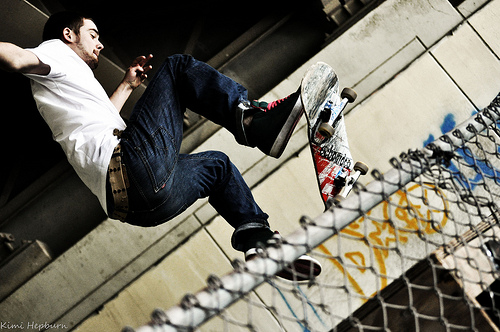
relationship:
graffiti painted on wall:
[291, 101, 499, 293] [4, 3, 498, 330]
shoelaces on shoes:
[262, 98, 292, 112] [252, 65, 306, 155]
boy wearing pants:
[2, 13, 322, 281] [107, 51, 269, 223]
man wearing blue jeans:
[2, 12, 371, 278] [110, 54, 310, 277]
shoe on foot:
[241, 84, 309, 159] [217, 30, 342, 167]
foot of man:
[217, 30, 342, 167] [2, 12, 371, 278]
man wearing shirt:
[2, 12, 371, 278] [24, 35, 125, 217]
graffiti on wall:
[291, 186, 466, 293] [4, 3, 498, 330]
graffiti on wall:
[291, 101, 499, 293] [4, 3, 498, 330]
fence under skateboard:
[121, 96, 498, 331] [301, 61, 368, 210]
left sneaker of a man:
[231, 222, 321, 287] [2, 12, 371, 278]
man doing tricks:
[2, 12, 371, 278] [1, 0, 389, 304]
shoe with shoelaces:
[241, 84, 309, 159] [262, 98, 292, 112]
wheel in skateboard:
[324, 194, 341, 209] [292, 58, 369, 215]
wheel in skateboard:
[351, 160, 371, 174] [292, 58, 369, 215]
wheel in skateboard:
[340, 86, 357, 103] [292, 58, 369, 215]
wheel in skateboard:
[317, 121, 335, 137] [292, 58, 369, 215]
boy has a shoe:
[2, 13, 322, 281] [176, 70, 373, 164]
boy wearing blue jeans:
[2, 13, 322, 281] [110, 54, 254, 226]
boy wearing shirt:
[2, 13, 322, 281] [32, 37, 133, 217]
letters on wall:
[317, 111, 497, 302] [4, 3, 498, 330]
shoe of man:
[241, 84, 309, 159] [2, 12, 371, 278]